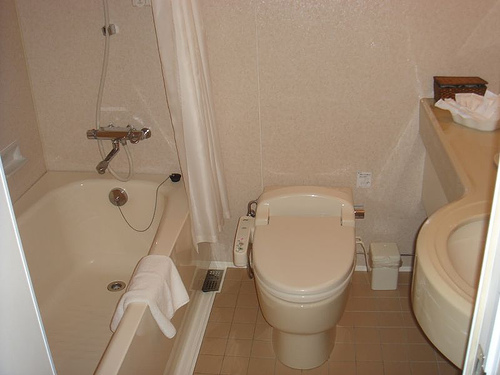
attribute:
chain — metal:
[109, 174, 168, 234]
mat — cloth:
[108, 254, 192, 334]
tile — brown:
[188, 264, 456, 370]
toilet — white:
[229, 183, 364, 366]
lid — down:
[250, 215, 356, 291]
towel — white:
[107, 252, 189, 337]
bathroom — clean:
[8, 7, 484, 368]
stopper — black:
[167, 170, 182, 184]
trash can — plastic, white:
[366, 234, 401, 290]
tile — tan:
[204, 302, 238, 322]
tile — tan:
[228, 303, 259, 323]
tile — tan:
[352, 324, 381, 343]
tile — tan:
[380, 342, 410, 361]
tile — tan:
[376, 308, 405, 327]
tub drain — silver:
[106, 278, 126, 293]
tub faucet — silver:
[85, 122, 152, 174]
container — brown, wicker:
[431, 74, 484, 104]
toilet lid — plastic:
[249, 212, 357, 296]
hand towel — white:
[108, 252, 191, 337]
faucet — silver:
[85, 122, 150, 174]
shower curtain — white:
[149, 1, 232, 254]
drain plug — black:
[167, 170, 181, 183]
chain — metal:
[114, 173, 174, 233]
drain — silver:
[106, 279, 126, 293]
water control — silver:
[84, 122, 152, 174]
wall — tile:
[2, 1, 48, 205]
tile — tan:
[222, 335, 256, 355]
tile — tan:
[248, 335, 279, 359]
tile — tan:
[353, 340, 383, 363]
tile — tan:
[407, 342, 437, 362]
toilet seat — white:
[251, 211, 356, 303]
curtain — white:
[151, 2, 233, 247]